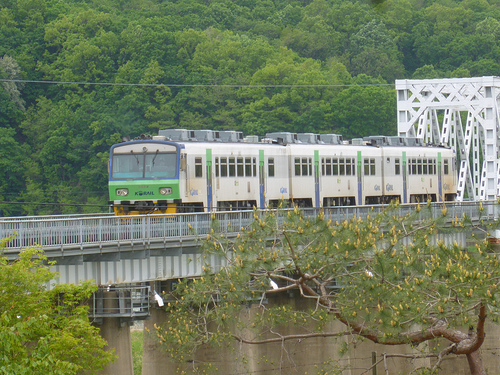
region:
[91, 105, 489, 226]
a passenger train going across a bridge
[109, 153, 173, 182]
the windshield of a passenger train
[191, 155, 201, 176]
a window on a passenger train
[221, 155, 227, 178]
a window on a passenger train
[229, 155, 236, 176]
a window on a passenger train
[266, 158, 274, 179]
a window on a passenger train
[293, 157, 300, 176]
a window on a passenger train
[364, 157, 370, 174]
a window on a passenger train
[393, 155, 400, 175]
a window on a passenger train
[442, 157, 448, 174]
a window on a passenger train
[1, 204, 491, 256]
The long metal bridge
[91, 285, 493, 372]
The brown pillars holding up the bridge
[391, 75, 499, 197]
The arch way above the bridge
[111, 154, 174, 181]
The front wind sheild on the bus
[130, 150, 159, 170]
The wind sheild wipers on the train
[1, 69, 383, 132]
The green trees behind the train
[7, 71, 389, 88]
The electrical lines above the train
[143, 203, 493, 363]
The tree with the yellow flowers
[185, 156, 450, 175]
The windows on the train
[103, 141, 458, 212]
The entire train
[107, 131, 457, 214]
A White and green train on a bridge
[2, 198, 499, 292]
A railway bridge across a river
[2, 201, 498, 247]
Railing on the bridge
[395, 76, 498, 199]
Metal pillars and beams supporting the bridge.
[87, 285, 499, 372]
Water under the bridge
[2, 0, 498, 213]
Thick green trees in the background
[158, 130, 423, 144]
Air conditioners on top of the train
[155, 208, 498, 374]
A tree with wild fruits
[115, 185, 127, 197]
One of the two headlights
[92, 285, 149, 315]
Maintenance deck under the bridge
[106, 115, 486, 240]
a white and green train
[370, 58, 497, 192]
the bridge is white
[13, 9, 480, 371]
picture taken outside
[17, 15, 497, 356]
picture taken outdoors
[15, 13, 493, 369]
picture taken during the day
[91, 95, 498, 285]
a train on the tracks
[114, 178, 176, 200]
the front of the train is green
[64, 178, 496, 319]
the tracks are above the water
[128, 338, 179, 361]
the water is brown in color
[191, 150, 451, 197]
the train holds passengers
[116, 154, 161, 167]
the train has wipers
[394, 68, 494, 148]
the bridge is white